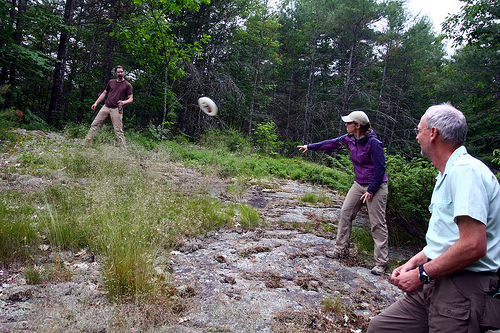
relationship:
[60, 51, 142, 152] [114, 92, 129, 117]
man has bottle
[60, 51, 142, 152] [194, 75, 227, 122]
man watches frisbee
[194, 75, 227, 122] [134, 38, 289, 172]
frisbee in air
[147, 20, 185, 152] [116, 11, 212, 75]
tree missing leaves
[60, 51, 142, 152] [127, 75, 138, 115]
man has arm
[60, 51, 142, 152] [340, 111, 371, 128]
man wearing cap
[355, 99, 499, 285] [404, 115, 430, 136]
man wearing glasses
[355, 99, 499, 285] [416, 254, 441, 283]
man wearing watch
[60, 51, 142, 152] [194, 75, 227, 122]
man going to catch frisbee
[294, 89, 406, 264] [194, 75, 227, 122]
woman throwing frisbee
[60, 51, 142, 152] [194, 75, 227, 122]
man watching frisbee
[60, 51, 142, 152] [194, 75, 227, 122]
man catch frisbee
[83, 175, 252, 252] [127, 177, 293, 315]
plants on ground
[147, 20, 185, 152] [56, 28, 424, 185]
tree in background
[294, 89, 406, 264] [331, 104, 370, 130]
woman wearing cap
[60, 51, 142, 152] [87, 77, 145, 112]
person wearing shirt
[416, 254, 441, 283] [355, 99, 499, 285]
watch on man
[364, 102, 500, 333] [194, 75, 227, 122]
man playing frisbee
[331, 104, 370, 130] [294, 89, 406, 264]
cap on women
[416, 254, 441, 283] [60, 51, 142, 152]
watch on man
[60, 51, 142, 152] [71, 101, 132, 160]
man has pants